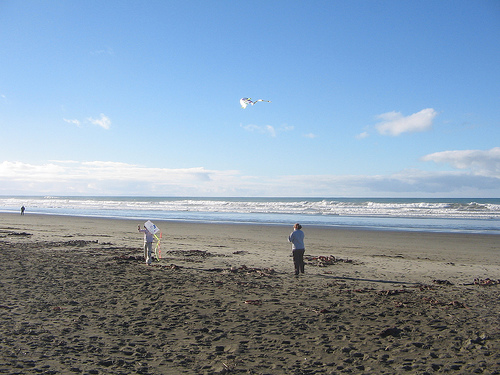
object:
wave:
[0, 197, 499, 221]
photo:
[0, 0, 500, 375]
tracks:
[40, 296, 47, 302]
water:
[0, 195, 500, 238]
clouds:
[404, 119, 429, 133]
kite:
[239, 96, 271, 109]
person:
[136, 223, 154, 265]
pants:
[144, 241, 152, 264]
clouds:
[158, 172, 172, 176]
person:
[20, 205, 26, 216]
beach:
[0, 209, 499, 371]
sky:
[0, 0, 500, 199]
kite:
[143, 219, 163, 262]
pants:
[292, 248, 306, 275]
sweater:
[287, 229, 306, 250]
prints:
[352, 304, 363, 309]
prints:
[57, 284, 63, 287]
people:
[287, 222, 306, 276]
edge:
[0, 210, 500, 286]